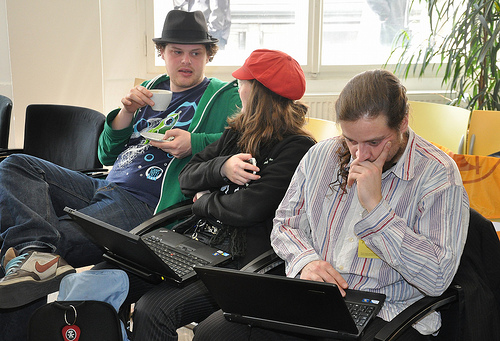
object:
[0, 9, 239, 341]
guy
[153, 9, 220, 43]
hat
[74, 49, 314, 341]
girl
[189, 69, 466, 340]
guy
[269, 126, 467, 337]
shirt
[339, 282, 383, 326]
keyboard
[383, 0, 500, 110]
tree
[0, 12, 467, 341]
them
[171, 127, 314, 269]
jacket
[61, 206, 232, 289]
laptop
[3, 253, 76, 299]
sneakers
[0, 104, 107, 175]
chair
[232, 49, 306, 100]
bill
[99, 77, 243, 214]
sweater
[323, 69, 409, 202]
hair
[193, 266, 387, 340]
laptop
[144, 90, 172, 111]
cup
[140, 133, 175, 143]
saucer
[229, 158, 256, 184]
phone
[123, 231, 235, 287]
lap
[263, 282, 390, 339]
lap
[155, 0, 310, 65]
window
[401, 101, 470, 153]
seat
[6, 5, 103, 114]
wall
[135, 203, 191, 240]
arm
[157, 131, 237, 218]
chair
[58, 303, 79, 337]
keychain